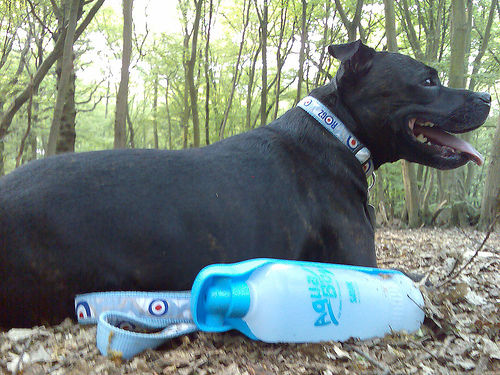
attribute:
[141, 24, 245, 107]
green trees — sparse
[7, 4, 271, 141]
trees — tall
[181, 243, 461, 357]
bottle — light blue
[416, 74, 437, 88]
eye — black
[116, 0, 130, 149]
tree — skinny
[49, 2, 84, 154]
tree — skinny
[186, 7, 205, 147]
tree — skinny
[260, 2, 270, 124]
tree — skinny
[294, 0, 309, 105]
tree — skinny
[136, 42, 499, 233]
dog — black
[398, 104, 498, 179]
mouth — open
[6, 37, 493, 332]
dog — black, big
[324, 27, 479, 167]
head — black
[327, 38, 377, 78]
ear — pointed